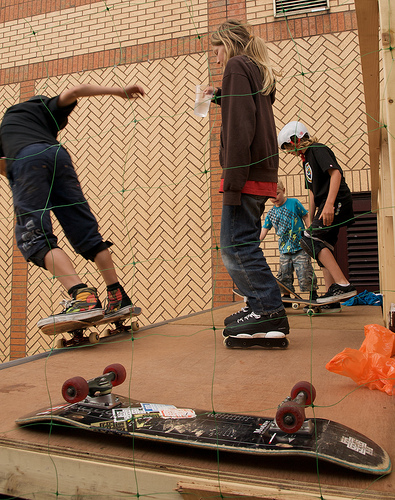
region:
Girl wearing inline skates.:
[216, 303, 292, 353]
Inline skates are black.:
[216, 293, 291, 354]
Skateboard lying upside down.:
[12, 354, 394, 474]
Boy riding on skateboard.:
[0, 70, 152, 352]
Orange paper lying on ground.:
[321, 320, 390, 390]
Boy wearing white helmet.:
[274, 113, 309, 155]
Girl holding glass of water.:
[187, 79, 214, 121]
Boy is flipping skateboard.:
[271, 115, 362, 318]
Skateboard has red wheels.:
[55, 356, 315, 430]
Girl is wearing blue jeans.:
[214, 187, 298, 322]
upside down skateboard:
[37, 359, 368, 485]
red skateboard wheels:
[247, 371, 351, 456]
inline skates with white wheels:
[200, 267, 315, 366]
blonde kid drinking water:
[156, 21, 295, 194]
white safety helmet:
[278, 116, 328, 172]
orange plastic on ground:
[346, 321, 393, 427]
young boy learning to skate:
[254, 177, 318, 299]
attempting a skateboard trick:
[10, 97, 161, 373]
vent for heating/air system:
[263, 2, 332, 25]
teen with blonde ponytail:
[196, 18, 280, 111]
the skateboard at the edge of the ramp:
[29, 307, 162, 340]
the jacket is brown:
[209, 51, 277, 206]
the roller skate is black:
[215, 304, 295, 352]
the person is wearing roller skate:
[197, 27, 295, 355]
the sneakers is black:
[315, 282, 365, 313]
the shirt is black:
[301, 151, 341, 217]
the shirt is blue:
[264, 198, 320, 275]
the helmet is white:
[274, 117, 315, 155]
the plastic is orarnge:
[328, 311, 394, 404]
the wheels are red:
[57, 361, 174, 405]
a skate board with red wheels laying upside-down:
[17, 371, 391, 485]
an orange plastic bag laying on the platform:
[323, 325, 393, 389]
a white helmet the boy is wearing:
[275, 117, 313, 145]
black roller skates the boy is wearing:
[206, 299, 310, 355]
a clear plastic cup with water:
[186, 81, 223, 121]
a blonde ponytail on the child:
[250, 33, 279, 99]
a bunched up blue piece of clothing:
[344, 290, 384, 310]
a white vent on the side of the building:
[269, 0, 344, 17]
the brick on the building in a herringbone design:
[95, 138, 198, 217]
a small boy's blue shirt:
[259, 206, 310, 256]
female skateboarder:
[208, 5, 310, 389]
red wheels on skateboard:
[58, 364, 181, 411]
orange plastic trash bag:
[327, 332, 393, 412]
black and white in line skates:
[227, 303, 322, 359]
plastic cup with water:
[169, 73, 238, 129]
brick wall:
[54, 35, 228, 203]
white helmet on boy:
[281, 121, 336, 173]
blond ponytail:
[214, 16, 300, 117]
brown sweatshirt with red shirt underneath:
[219, 59, 275, 220]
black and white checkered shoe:
[307, 270, 374, 304]